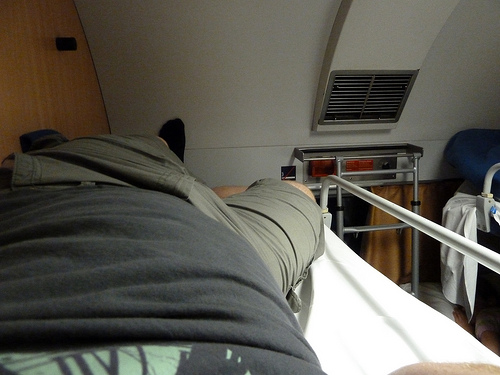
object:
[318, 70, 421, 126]
air vent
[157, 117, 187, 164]
sock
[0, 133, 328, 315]
shorts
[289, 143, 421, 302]
ladder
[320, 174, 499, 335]
rail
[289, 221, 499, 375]
sheet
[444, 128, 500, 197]
pillow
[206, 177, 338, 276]
leg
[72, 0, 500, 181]
wall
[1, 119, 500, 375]
man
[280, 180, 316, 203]
knee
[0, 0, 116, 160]
pael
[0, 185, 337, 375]
shirt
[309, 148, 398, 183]
machier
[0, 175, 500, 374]
bed